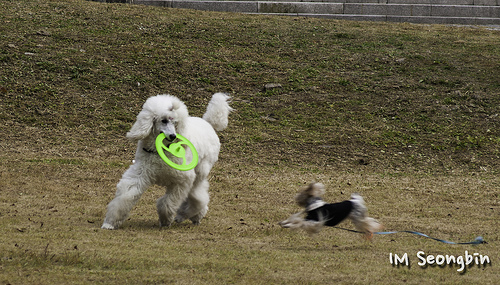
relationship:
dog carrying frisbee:
[111, 128, 196, 130] [144, 146, 183, 157]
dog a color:
[100, 92, 235, 230] [192, 126, 207, 144]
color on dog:
[192, 126, 207, 144] [100, 92, 235, 230]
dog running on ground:
[278, 182, 386, 240] [0, 0, 497, 282]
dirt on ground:
[0, 128, 499, 283] [0, 0, 497, 282]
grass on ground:
[0, 0, 497, 282] [0, 0, 497, 282]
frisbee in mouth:
[152, 133, 202, 168] [153, 128, 173, 145]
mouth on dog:
[153, 128, 173, 145] [100, 92, 235, 230]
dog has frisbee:
[100, 92, 235, 230] [152, 133, 202, 168]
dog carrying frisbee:
[100, 92, 235, 230] [153, 130, 196, 171]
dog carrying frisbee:
[100, 92, 235, 230] [154, 128, 200, 171]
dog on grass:
[100, 92, 235, 230] [0, 0, 497, 282]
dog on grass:
[278, 182, 386, 240] [0, 0, 497, 282]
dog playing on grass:
[278, 182, 386, 240] [44, 170, 444, 267]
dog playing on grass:
[278, 182, 386, 240] [43, 153, 451, 274]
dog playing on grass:
[289, 171, 382, 244] [43, 153, 451, 274]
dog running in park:
[278, 182, 386, 240] [34, 30, 478, 259]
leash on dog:
[400, 225, 459, 248] [289, 177, 389, 233]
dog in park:
[100, 92, 235, 230] [35, 18, 481, 248]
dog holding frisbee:
[100, 92, 235, 230] [145, 127, 205, 169]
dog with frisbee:
[100, 92, 235, 230] [154, 128, 200, 171]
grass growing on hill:
[21, 33, 444, 84] [30, 6, 497, 106]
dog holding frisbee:
[100, 92, 235, 230] [153, 130, 213, 176]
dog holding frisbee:
[100, 92, 235, 230] [150, 123, 200, 183]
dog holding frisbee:
[100, 92, 235, 230] [160, 131, 195, 182]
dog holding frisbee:
[100, 92, 235, 230] [152, 126, 196, 173]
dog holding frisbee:
[100, 92, 235, 230] [158, 132, 207, 183]